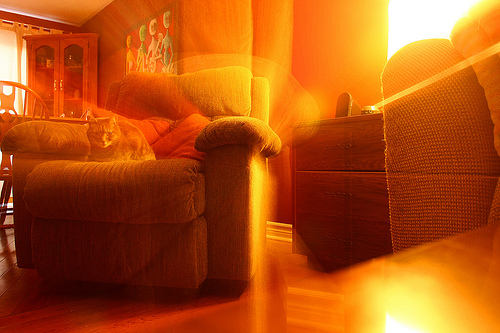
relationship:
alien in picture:
[135, 24, 150, 71] [120, 2, 180, 80]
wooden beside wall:
[313, 128, 379, 243] [268, 0, 383, 247]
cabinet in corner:
[20, 32, 103, 119] [18, 15, 104, 125]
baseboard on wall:
[261, 215, 302, 246] [258, 4, 388, 217]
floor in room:
[7, 219, 498, 331] [3, 4, 499, 330]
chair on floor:
[35, 30, 353, 302] [7, 219, 498, 331]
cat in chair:
[83, 112, 156, 161] [0, 64, 283, 305]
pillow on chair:
[137, 113, 210, 159] [0, 64, 283, 305]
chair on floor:
[0, 64, 283, 305] [68, 282, 158, 327]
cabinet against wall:
[20, 33, 99, 120] [3, 2, 162, 107]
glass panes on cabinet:
[30, 44, 84, 120] [20, 32, 103, 119]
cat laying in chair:
[85, 113, 157, 163] [2, 62, 291, 310]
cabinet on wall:
[294, 114, 396, 266] [53, 0, 390, 257]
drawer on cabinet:
[290, 118, 389, 173] [284, 110, 393, 265]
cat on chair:
[83, 112, 156, 161] [12, 78, 290, 300]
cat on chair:
[85, 113, 157, 163] [0, 64, 283, 305]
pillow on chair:
[150, 111, 214, 163] [0, 64, 283, 305]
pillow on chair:
[91, 106, 169, 146] [0, 64, 283, 305]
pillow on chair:
[80, 98, 170, 140] [0, 64, 283, 305]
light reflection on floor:
[351, 268, 469, 330] [7, 219, 498, 331]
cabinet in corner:
[20, 33, 99, 120] [22, 6, 111, 116]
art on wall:
[117, 16, 176, 83] [177, 5, 252, 87]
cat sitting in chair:
[85, 113, 157, 163] [0, 64, 283, 305]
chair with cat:
[0, 64, 283, 305] [85, 113, 157, 163]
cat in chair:
[85, 113, 157, 163] [4, 68, 275, 315]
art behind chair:
[122, 0, 181, 76] [0, 64, 283, 305]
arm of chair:
[376, 39, 498, 249] [370, 12, 498, 319]